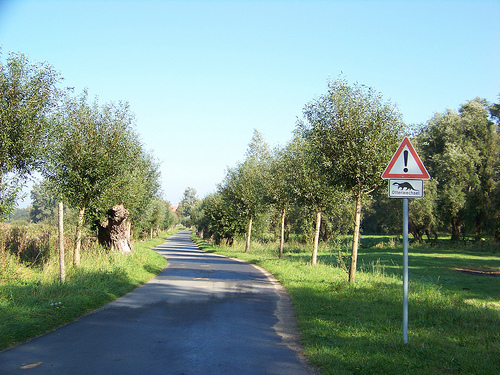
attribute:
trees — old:
[5, 46, 495, 281]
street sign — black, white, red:
[373, 135, 433, 185]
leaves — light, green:
[312, 112, 389, 183]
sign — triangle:
[366, 134, 463, 229]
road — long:
[14, 203, 324, 372]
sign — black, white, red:
[379, 135, 439, 182]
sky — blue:
[18, 7, 498, 108]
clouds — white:
[173, 72, 219, 123]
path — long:
[17, 217, 318, 372]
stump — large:
[96, 204, 132, 256]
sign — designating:
[381, 133, 433, 200]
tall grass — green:
[85, 253, 152, 303]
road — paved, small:
[0, 156, 324, 373]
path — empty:
[102, 222, 281, 372]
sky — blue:
[13, 6, 496, 79]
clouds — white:
[163, 141, 234, 177]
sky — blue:
[3, 1, 495, 49]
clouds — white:
[119, 57, 277, 180]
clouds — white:
[135, 70, 255, 191]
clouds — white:
[104, 39, 251, 179]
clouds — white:
[110, 53, 257, 178]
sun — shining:
[42, 13, 322, 149]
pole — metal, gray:
[399, 194, 411, 346]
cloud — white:
[8, 139, 294, 218]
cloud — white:
[7, 133, 298, 211]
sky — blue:
[0, 2, 498, 208]